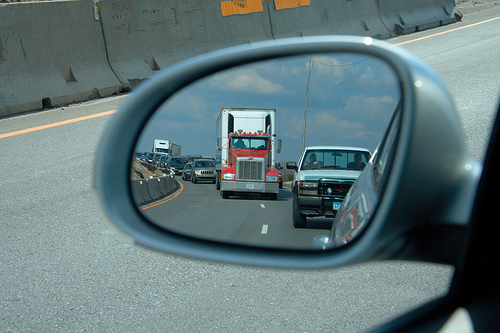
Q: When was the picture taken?
A: Daytime.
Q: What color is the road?
A: Gray.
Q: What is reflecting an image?
A: The mirror.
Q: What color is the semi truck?
A: Red.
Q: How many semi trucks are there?
A: One.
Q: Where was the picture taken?
A: In a car.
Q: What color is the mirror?
A: Silver.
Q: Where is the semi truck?
A: On the road.